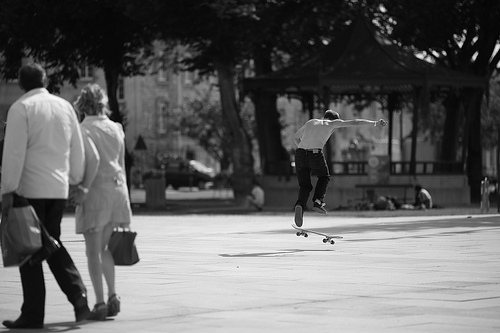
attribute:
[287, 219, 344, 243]
skateboard — airborne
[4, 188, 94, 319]
pants — black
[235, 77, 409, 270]
skateboarder — shirtless 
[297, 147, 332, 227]
pants — dark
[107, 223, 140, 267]
purse — large 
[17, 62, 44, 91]
hair — dark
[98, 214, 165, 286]
handbag — dark colored